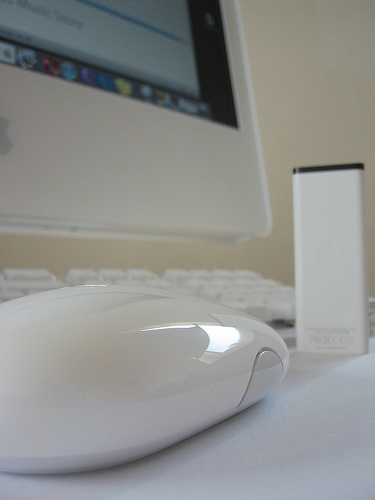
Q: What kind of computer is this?
A: A Mac.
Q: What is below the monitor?
A: A keyboard.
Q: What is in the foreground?
A: A white mouse.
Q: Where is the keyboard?
A: Under the monitor.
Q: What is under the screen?
A: Keyboard.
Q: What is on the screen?
A: Taskbar.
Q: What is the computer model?
A: Imac.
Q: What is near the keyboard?
A: A mouse.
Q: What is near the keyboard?
A: Apple remote.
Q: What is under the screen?
A: Keyboard.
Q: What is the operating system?
A: Apple Mac.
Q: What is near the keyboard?
A: Mouse.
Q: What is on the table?
A: A mouse.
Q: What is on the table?
A: A speaker.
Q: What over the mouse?
A: A white monitor.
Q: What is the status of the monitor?
A: Monitor is on.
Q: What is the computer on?
A: A white table.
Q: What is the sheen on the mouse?
A: The mouse is shiny.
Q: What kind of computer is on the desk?
A: A mac computer.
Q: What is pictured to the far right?
A: A speaker.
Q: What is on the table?
A: A computer.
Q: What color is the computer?
A: White.